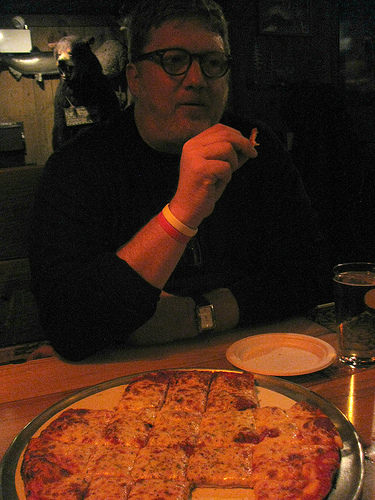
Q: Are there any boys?
A: No, there are no boys.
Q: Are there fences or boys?
A: No, there are no boys or fences.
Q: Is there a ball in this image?
A: No, there are no balls.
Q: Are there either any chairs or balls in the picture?
A: No, there are no balls or chairs.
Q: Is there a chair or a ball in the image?
A: No, there are no balls or chairs.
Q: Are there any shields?
A: No, there are no shields.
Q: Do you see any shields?
A: No, there are no shields.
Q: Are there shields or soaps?
A: No, there are no shields or soaps.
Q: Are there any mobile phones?
A: No, there are no mobile phones.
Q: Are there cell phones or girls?
A: No, there are no cell phones or girls.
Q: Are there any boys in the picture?
A: No, there are no boys.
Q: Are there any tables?
A: Yes, there is a table.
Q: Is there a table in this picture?
A: Yes, there is a table.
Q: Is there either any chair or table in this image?
A: Yes, there is a table.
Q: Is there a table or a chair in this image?
A: Yes, there is a table.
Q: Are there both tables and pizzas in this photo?
A: Yes, there are both a table and a pizza.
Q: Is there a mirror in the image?
A: No, there are no mirrors.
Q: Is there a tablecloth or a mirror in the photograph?
A: No, there are no mirrors or tablecloths.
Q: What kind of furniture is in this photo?
A: The furniture is a table.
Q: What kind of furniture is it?
A: The piece of furniture is a table.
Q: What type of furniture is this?
A: This is a table.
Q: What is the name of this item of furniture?
A: This is a table.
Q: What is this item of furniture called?
A: This is a table.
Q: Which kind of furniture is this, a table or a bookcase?
A: This is a table.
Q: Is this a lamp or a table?
A: This is a table.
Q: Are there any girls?
A: No, there are no girls.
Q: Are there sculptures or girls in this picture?
A: No, there are no girls or sculptures.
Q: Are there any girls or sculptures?
A: No, there are no girls or sculptures.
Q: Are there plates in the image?
A: Yes, there is a plate.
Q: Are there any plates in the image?
A: Yes, there is a plate.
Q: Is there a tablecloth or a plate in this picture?
A: Yes, there is a plate.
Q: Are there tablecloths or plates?
A: Yes, there is a plate.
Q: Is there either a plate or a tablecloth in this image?
A: Yes, there is a plate.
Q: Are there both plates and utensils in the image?
A: No, there is a plate but no utensils.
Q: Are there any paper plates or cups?
A: Yes, there is a paper plate.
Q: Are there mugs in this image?
A: No, there are no mugs.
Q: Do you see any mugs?
A: No, there are no mugs.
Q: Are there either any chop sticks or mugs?
A: No, there are no mugs or chop sticks.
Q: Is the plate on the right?
A: Yes, the plate is on the right of the image.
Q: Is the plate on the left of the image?
A: No, the plate is on the right of the image.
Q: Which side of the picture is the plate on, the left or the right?
A: The plate is on the right of the image.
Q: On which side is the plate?
A: The plate is on the right of the image.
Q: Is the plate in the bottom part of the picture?
A: Yes, the plate is in the bottom of the image.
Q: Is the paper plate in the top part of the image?
A: No, the plate is in the bottom of the image.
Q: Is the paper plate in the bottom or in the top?
A: The plate is in the bottom of the image.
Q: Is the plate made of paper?
A: Yes, the plate is made of paper.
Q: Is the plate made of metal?
A: No, the plate is made of paper.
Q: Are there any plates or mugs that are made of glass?
A: No, there is a plate but it is made of paper.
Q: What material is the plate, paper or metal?
A: The plate is made of paper.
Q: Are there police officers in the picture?
A: No, there are no police officers.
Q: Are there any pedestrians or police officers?
A: No, there are no police officers or pedestrians.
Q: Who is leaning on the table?
A: The man is leaning on the table.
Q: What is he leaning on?
A: The man is leaning on the table.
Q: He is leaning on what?
A: The man is leaning on the table.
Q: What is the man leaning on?
A: The man is leaning on the table.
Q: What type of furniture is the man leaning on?
A: The man is leaning on the table.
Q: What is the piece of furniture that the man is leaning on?
A: The piece of furniture is a table.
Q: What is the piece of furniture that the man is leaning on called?
A: The piece of furniture is a table.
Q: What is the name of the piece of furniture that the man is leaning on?
A: The piece of furniture is a table.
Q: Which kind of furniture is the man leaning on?
A: The man is leaning on the table.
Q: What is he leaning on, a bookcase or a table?
A: The man is leaning on a table.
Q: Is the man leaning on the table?
A: Yes, the man is leaning on the table.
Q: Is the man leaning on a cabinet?
A: No, the man is leaning on the table.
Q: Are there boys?
A: No, there are no boys.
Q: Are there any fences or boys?
A: No, there are no boys or fences.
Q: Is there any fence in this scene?
A: No, there are no fences.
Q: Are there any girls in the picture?
A: No, there are no girls.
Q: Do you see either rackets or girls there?
A: No, there are no girls or rackets.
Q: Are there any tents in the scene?
A: No, there are no tents.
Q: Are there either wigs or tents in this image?
A: No, there are no tents or wigs.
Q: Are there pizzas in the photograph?
A: Yes, there is a pizza.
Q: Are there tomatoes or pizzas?
A: Yes, there is a pizza.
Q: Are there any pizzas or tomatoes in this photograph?
A: Yes, there is a pizza.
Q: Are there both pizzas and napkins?
A: No, there is a pizza but no napkins.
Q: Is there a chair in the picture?
A: No, there are no chairs.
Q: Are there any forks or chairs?
A: No, there are no chairs or forks.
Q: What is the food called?
A: The food is a pizza.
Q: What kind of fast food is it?
A: The food is a pizza.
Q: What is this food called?
A: This is a pizza.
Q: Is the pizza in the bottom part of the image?
A: Yes, the pizza is in the bottom of the image.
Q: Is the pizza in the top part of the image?
A: No, the pizza is in the bottom of the image.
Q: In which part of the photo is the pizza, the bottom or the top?
A: The pizza is in the bottom of the image.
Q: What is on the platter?
A: The pizza is on the platter.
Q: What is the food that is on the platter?
A: The food is a pizza.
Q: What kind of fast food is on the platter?
A: The food is a pizza.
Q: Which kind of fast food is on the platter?
A: The food is a pizza.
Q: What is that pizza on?
A: The pizza is on the platter.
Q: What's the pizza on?
A: The pizza is on the platter.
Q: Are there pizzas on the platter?
A: Yes, there is a pizza on the platter.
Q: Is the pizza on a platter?
A: Yes, the pizza is on a platter.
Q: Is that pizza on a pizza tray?
A: No, the pizza is on a platter.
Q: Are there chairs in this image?
A: No, there are no chairs.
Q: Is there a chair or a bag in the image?
A: No, there are no chairs or bags.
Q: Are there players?
A: No, there are no players.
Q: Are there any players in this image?
A: No, there are no players.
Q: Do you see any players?
A: No, there are no players.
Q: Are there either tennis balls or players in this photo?
A: No, there are no players or tennis balls.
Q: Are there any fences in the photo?
A: No, there are no fences.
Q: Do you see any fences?
A: No, there are no fences.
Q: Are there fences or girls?
A: No, there are no fences or girls.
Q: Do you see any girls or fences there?
A: No, there are no fences or girls.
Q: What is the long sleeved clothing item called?
A: The clothing item is a shirt.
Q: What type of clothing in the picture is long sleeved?
A: The clothing is a shirt.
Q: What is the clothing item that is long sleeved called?
A: The clothing item is a shirt.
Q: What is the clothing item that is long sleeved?
A: The clothing item is a shirt.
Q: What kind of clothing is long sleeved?
A: The clothing is a shirt.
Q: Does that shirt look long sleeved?
A: Yes, the shirt is long sleeved.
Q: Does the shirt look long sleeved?
A: Yes, the shirt is long sleeved.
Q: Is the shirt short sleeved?
A: No, the shirt is long sleeved.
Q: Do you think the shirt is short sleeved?
A: No, the shirt is long sleeved.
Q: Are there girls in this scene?
A: No, there are no girls.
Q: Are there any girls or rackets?
A: No, there are no girls or rackets.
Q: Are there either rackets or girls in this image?
A: No, there are no girls or rackets.